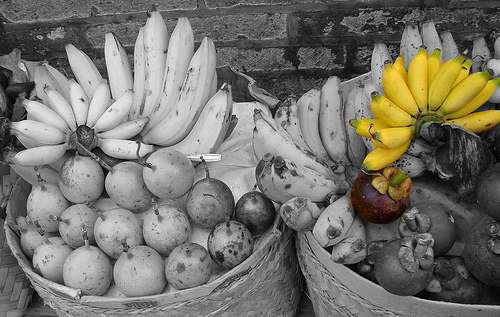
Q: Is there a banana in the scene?
A: Yes, there is a banana.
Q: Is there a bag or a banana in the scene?
A: Yes, there is a banana.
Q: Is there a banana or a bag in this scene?
A: Yes, there is a banana.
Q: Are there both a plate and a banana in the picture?
A: No, there is a banana but no plates.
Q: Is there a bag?
A: No, there are no bags.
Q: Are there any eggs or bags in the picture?
A: No, there are no bags or eggs.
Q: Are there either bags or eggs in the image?
A: No, there are no bags or eggs.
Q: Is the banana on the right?
A: Yes, the banana is on the right of the image.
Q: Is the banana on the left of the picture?
A: No, the banana is on the right of the image.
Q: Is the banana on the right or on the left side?
A: The banana is on the right of the image.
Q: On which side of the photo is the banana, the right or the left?
A: The banana is on the right of the image.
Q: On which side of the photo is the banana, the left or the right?
A: The banana is on the right of the image.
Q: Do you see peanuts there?
A: No, there are no peanuts.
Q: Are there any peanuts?
A: No, there are no peanuts.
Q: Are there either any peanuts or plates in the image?
A: No, there are no peanuts or plates.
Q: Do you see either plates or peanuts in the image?
A: No, there are no peanuts or plates.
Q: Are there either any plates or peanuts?
A: No, there are no peanuts or plates.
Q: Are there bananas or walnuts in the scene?
A: Yes, there is a banana.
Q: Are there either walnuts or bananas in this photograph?
A: Yes, there is a banana.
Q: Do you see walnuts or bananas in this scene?
A: Yes, there is a banana.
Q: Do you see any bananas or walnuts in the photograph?
A: Yes, there is a banana.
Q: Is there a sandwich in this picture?
A: No, there are no sandwiches.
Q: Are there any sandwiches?
A: No, there are no sandwiches.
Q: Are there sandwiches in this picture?
A: No, there are no sandwiches.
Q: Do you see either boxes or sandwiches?
A: No, there are no sandwiches or boxes.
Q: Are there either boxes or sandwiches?
A: No, there are no sandwiches or boxes.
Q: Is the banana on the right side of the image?
A: Yes, the banana is on the right of the image.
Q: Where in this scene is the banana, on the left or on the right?
A: The banana is on the right of the image.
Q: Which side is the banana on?
A: The banana is on the right of the image.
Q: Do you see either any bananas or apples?
A: Yes, there is a banana.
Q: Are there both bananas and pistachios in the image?
A: No, there is a banana but no pistachios.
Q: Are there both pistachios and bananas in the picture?
A: No, there is a banana but no pistachios.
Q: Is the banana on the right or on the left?
A: The banana is on the right of the image.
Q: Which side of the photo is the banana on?
A: The banana is on the right of the image.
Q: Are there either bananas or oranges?
A: Yes, there is a banana.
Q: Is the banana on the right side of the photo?
A: Yes, the banana is on the right of the image.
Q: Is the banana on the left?
A: No, the banana is on the right of the image.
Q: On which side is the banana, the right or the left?
A: The banana is on the right of the image.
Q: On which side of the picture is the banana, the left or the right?
A: The banana is on the right of the image.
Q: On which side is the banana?
A: The banana is on the right of the image.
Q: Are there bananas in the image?
A: Yes, there is a banana.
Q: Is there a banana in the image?
A: Yes, there is a banana.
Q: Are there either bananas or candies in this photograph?
A: Yes, there is a banana.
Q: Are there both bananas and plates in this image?
A: No, there is a banana but no plates.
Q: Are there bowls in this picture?
A: No, there are no bowls.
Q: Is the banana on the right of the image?
A: Yes, the banana is on the right of the image.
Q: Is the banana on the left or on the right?
A: The banana is on the right of the image.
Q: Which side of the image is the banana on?
A: The banana is on the right of the image.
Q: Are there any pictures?
A: No, there are no pictures.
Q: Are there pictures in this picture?
A: No, there are no pictures.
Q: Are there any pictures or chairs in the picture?
A: No, there are no pictures or chairs.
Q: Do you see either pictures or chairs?
A: No, there are no pictures or chairs.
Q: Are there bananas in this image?
A: Yes, there is a banana.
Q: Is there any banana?
A: Yes, there is a banana.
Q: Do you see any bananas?
A: Yes, there is a banana.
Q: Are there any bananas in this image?
A: Yes, there is a banana.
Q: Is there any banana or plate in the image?
A: Yes, there is a banana.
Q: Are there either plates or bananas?
A: Yes, there is a banana.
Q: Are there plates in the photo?
A: No, there are no plates.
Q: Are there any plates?
A: No, there are no plates.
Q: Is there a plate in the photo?
A: No, there are no plates.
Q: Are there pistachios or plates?
A: No, there are no plates or pistachios.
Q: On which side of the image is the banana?
A: The banana is on the right of the image.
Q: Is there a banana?
A: Yes, there is a banana.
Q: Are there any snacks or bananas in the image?
A: Yes, there is a banana.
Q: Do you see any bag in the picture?
A: No, there are no bags.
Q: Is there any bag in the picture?
A: No, there are no bags.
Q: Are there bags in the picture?
A: No, there are no bags.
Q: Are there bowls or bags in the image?
A: No, there are no bags or bowls.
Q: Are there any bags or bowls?
A: No, there are no bags or bowls.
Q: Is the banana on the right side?
A: Yes, the banana is on the right of the image.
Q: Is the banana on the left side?
A: No, the banana is on the right of the image.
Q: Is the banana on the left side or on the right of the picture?
A: The banana is on the right of the image.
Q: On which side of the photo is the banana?
A: The banana is on the right of the image.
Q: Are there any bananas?
A: Yes, there are bananas.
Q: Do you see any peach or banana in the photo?
A: Yes, there are bananas.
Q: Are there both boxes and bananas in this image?
A: No, there are bananas but no boxes.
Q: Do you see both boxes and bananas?
A: No, there are bananas but no boxes.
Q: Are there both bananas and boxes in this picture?
A: No, there are bananas but no boxes.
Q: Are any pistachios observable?
A: No, there are no pistachios.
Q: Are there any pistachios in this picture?
A: No, there are no pistachios.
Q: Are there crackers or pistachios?
A: No, there are no pistachios or crackers.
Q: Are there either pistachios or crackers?
A: No, there are no pistachios or crackers.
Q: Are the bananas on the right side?
A: Yes, the bananas are on the right of the image.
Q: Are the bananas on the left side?
A: No, the bananas are on the right of the image.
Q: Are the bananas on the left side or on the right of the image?
A: The bananas are on the right of the image.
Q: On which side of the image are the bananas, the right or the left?
A: The bananas are on the right of the image.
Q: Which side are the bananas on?
A: The bananas are on the right of the image.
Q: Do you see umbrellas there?
A: No, there are no umbrellas.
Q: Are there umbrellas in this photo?
A: No, there are no umbrellas.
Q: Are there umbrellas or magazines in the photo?
A: No, there are no umbrellas or magazines.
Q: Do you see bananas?
A: Yes, there is a banana.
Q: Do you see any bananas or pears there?
A: Yes, there is a banana.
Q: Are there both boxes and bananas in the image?
A: No, there is a banana but no boxes.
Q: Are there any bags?
A: No, there are no bags.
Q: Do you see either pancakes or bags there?
A: No, there are no bags or pancakes.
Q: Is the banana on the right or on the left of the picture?
A: The banana is on the right of the image.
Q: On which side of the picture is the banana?
A: The banana is on the right of the image.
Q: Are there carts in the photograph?
A: No, there are no carts.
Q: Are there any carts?
A: No, there are no carts.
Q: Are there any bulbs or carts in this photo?
A: No, there are no carts or bulbs.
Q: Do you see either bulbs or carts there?
A: No, there are no carts or bulbs.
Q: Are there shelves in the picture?
A: No, there are no shelves.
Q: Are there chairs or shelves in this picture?
A: No, there are no shelves or chairs.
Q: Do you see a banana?
A: Yes, there are bananas.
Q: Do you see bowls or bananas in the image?
A: Yes, there are bananas.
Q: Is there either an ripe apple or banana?
A: Yes, there are ripe bananas.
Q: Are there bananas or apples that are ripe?
A: Yes, the bananas are ripe.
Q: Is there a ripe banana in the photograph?
A: Yes, there are ripe bananas.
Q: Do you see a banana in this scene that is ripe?
A: Yes, there are bananas that are ripe.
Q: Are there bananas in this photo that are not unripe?
A: Yes, there are ripe bananas.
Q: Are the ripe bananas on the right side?
A: Yes, the bananas are on the right of the image.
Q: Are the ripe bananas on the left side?
A: No, the bananas are on the right of the image.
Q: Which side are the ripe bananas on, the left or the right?
A: The bananas are on the right of the image.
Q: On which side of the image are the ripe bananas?
A: The bananas are on the right of the image.